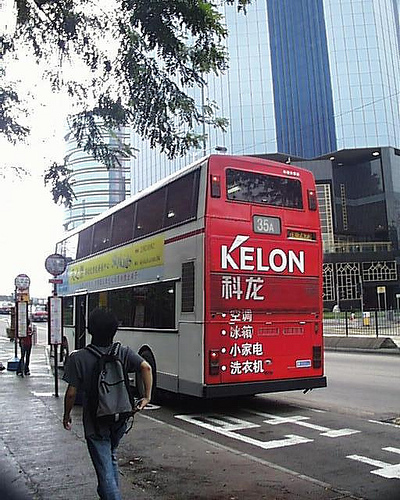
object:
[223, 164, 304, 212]
back window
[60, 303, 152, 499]
man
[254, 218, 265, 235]
number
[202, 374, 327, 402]
bumper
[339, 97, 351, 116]
windows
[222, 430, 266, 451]
lines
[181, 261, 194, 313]
vent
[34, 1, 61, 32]
tree limb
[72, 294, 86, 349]
door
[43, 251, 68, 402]
stop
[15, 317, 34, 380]
someone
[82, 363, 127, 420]
jeans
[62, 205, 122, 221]
second story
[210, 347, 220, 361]
light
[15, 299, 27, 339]
sign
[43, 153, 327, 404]
bus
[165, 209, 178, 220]
light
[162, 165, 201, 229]
window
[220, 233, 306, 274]
name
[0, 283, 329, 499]
bus stop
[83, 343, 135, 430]
backpack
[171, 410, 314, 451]
street sign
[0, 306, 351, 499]
sidewalk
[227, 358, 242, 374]
writing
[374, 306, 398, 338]
fence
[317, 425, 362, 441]
white line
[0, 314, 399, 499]
road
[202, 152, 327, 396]
back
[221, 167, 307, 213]
windshield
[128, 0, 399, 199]
building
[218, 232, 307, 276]
word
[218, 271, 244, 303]
foreign language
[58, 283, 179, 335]
window